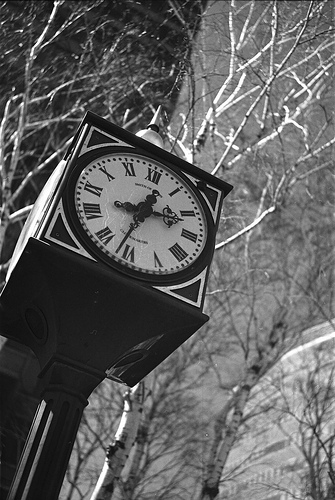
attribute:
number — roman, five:
[152, 247, 163, 267]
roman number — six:
[118, 239, 138, 263]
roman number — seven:
[92, 221, 121, 249]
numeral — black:
[177, 225, 200, 242]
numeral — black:
[148, 247, 163, 269]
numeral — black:
[96, 219, 114, 245]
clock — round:
[64, 144, 217, 281]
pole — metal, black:
[12, 353, 96, 498]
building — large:
[204, 321, 323, 484]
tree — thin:
[214, 169, 282, 497]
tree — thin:
[280, 342, 325, 496]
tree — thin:
[316, 434, 325, 458]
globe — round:
[135, 123, 170, 151]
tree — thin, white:
[89, 387, 149, 497]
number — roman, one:
[166, 182, 183, 197]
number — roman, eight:
[84, 201, 102, 221]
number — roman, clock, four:
[169, 238, 193, 266]